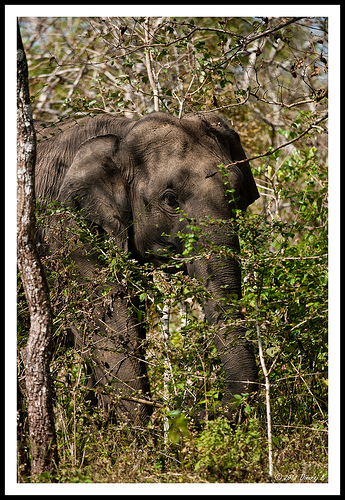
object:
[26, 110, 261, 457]
elephant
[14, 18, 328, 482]
photo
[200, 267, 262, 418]
trunk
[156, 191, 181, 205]
eye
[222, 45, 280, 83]
twigs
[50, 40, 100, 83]
branches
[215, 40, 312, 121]
trees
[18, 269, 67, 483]
tree trunk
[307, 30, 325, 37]
sky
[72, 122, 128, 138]
skin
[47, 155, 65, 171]
wrinkles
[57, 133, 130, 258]
ears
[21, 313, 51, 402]
stem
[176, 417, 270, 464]
bushes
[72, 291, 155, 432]
leg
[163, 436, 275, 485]
ground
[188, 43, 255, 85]
woods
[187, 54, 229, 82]
leaves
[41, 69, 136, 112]
forest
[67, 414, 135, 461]
bush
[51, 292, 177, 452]
legs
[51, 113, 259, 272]
head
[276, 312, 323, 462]
brush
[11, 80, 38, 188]
tree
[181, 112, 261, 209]
ear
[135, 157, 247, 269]
face